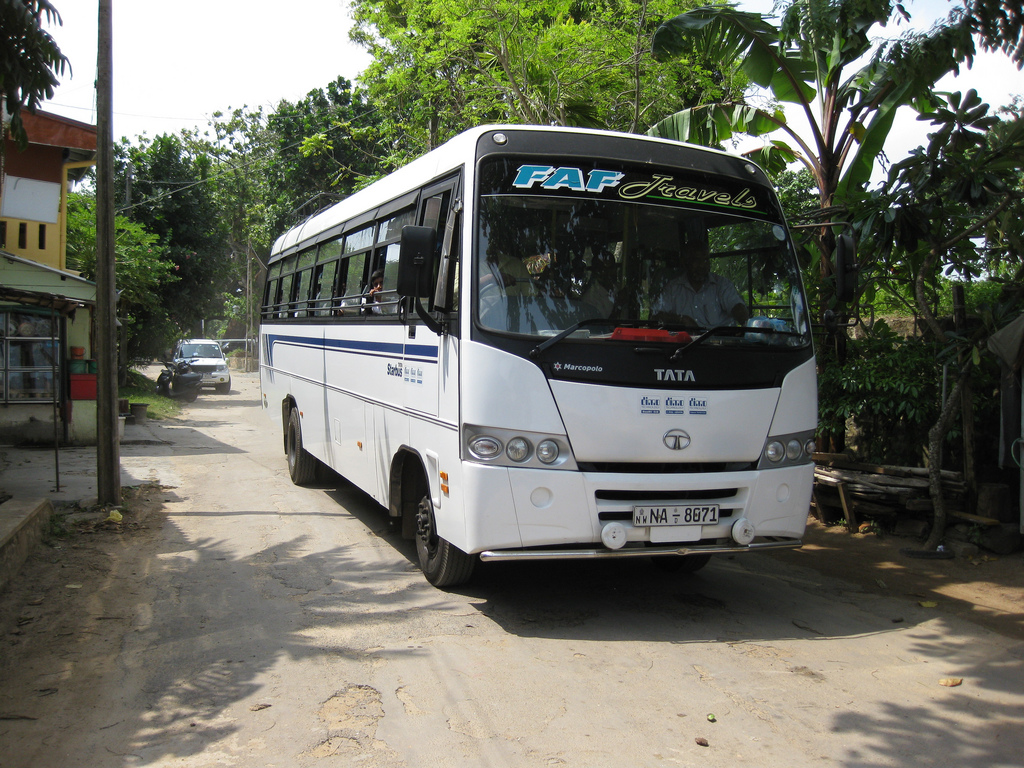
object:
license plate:
[633, 504, 719, 526]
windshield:
[469, 196, 814, 351]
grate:
[594, 487, 748, 554]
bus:
[258, 122, 823, 588]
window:
[360, 245, 388, 316]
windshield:
[469, 151, 812, 347]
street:
[0, 338, 1019, 764]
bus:
[259, 125, 817, 589]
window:
[19, 221, 28, 249]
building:
[0, 95, 111, 486]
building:
[0, 247, 116, 448]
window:
[39, 224, 46, 250]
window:
[7, 339, 60, 370]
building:
[0, 99, 109, 451]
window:
[6, 307, 59, 338]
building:
[0, 139, 110, 470]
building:
[0, 242, 113, 499]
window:
[6, 371, 64, 404]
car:
[173, 339, 232, 395]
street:
[0, 444, 430, 761]